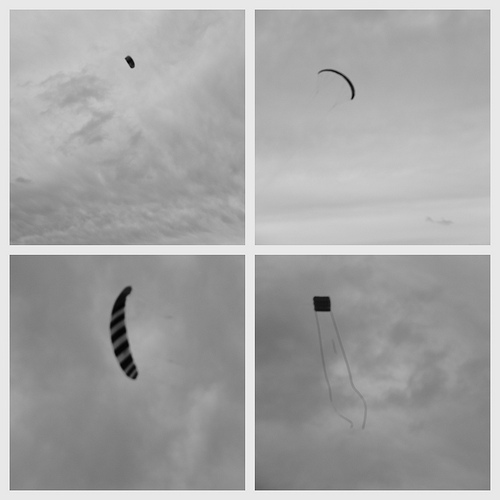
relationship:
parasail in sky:
[99, 278, 150, 383] [8, 257, 244, 491]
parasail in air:
[309, 59, 362, 106] [255, 10, 489, 241]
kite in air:
[298, 283, 373, 436] [257, 256, 491, 490]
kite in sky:
[298, 283, 373, 436] [368, 268, 459, 383]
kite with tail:
[298, 283, 373, 436] [308, 311, 371, 432]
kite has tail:
[298, 283, 373, 436] [308, 311, 371, 432]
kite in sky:
[123, 51, 139, 71] [8, 10, 244, 243]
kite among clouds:
[123, 51, 139, 71] [51, 25, 216, 234]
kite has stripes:
[95, 270, 160, 389] [116, 315, 129, 357]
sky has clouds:
[368, 268, 459, 383] [51, 25, 216, 234]